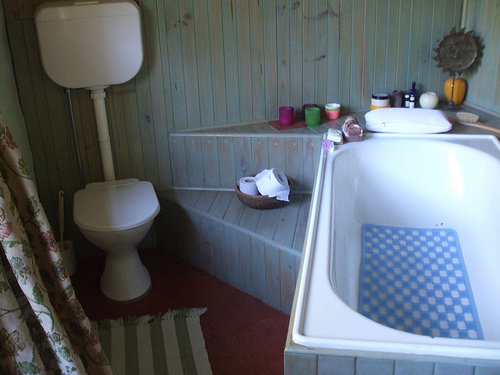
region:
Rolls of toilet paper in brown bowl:
[233, 165, 295, 210]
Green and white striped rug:
[106, 315, 191, 374]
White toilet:
[70, 168, 167, 310]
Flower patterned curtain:
[10, 198, 57, 353]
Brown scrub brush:
[452, 109, 495, 130]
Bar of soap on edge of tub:
[328, 123, 343, 147]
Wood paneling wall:
[165, 11, 404, 82]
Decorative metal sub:
[427, 18, 486, 83]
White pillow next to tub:
[366, 108, 455, 138]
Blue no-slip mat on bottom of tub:
[361, 218, 476, 323]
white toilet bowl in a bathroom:
[70, 173, 177, 298]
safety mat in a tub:
[356, 214, 481, 339]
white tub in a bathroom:
[284, 123, 497, 362]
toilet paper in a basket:
[233, 161, 293, 208]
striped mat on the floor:
[101, 306, 219, 373]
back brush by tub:
[451, 106, 496, 137]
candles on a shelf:
[269, 102, 327, 133]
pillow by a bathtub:
[363, 99, 450, 146]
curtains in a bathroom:
[3, 126, 104, 373]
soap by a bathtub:
[323, 123, 343, 147]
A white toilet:
[76, 181, 175, 300]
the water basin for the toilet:
[27, 1, 150, 98]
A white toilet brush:
[51, 192, 76, 273]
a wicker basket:
[231, 182, 288, 209]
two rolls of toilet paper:
[239, 166, 288, 196]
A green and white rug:
[84, 310, 216, 374]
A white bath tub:
[293, 132, 498, 352]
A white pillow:
[365, 108, 452, 135]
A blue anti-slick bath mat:
[356, 215, 483, 337]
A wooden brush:
[455, 111, 496, 133]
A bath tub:
[297, 135, 497, 363]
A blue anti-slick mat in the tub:
[363, 217, 483, 344]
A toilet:
[61, 173, 196, 298]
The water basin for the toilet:
[35, 0, 152, 119]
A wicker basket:
[236, 172, 297, 210]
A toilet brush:
[54, 191, 74, 269]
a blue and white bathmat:
[357, 222, 479, 339]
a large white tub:
[294, 133, 499, 351]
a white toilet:
[74, 175, 168, 300]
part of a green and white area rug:
[90, 309, 220, 373]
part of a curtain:
[0, 130, 125, 374]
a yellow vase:
[445, 76, 467, 102]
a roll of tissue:
[257, 170, 288, 194]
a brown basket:
[235, 187, 277, 207]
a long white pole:
[90, 91, 122, 180]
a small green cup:
[302, 105, 320, 122]